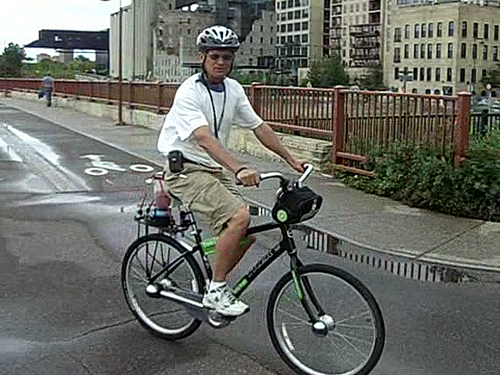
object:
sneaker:
[198, 278, 252, 319]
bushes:
[318, 134, 499, 218]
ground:
[0, 97, 500, 375]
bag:
[269, 183, 325, 225]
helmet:
[196, 22, 242, 48]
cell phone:
[168, 149, 183, 172]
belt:
[183, 158, 194, 164]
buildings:
[110, 0, 498, 114]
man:
[152, 24, 319, 317]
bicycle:
[116, 156, 399, 373]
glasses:
[209, 53, 234, 61]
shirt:
[156, 71, 269, 174]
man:
[39, 71, 56, 108]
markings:
[78, 153, 155, 177]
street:
[0, 105, 500, 374]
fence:
[0, 73, 470, 184]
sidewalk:
[0, 89, 500, 277]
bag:
[37, 89, 47, 99]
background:
[290, 53, 378, 100]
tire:
[261, 261, 387, 375]